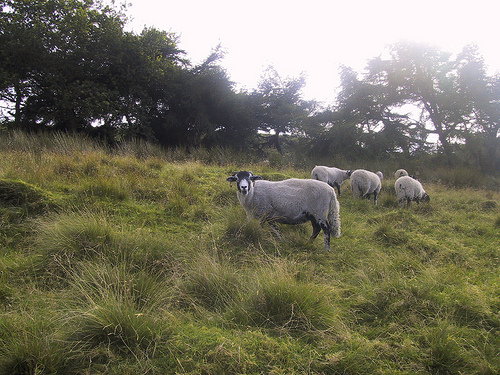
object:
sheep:
[393, 175, 430, 210]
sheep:
[311, 165, 354, 196]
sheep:
[393, 168, 408, 180]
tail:
[327, 190, 341, 238]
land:
[0, 157, 499, 373]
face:
[235, 170, 253, 197]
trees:
[0, 0, 135, 128]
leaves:
[265, 93, 290, 114]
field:
[0, 0, 499, 373]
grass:
[407, 272, 488, 329]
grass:
[177, 233, 277, 290]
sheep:
[226, 169, 341, 251]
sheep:
[349, 168, 382, 205]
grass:
[0, 156, 92, 198]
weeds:
[0, 247, 210, 374]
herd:
[224, 163, 430, 248]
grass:
[26, 255, 125, 332]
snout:
[240, 185, 246, 190]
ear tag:
[228, 180, 236, 187]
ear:
[224, 174, 237, 184]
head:
[224, 170, 261, 197]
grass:
[127, 144, 212, 194]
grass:
[449, 189, 498, 246]